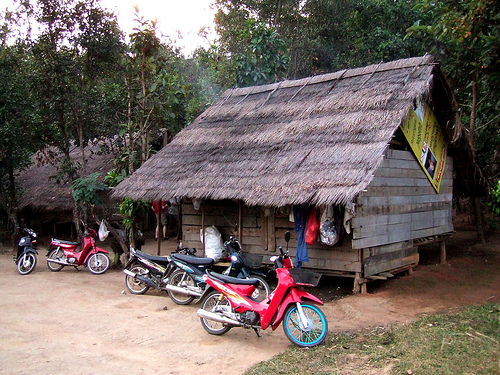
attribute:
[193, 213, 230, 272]
bag — another bag, laundry bag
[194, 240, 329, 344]
scooter — white, red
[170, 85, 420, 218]
roof — thatched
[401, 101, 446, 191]
sign — metal sign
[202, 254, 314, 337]
scooter — five